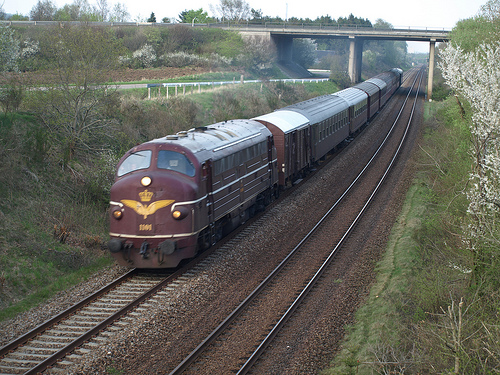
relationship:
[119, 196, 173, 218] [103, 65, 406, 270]
bird on train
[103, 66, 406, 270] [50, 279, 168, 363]
train on tracks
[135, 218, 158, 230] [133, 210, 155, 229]
1305 are numbers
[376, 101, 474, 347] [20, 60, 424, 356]
grass beside track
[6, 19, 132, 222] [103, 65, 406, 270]
trees by train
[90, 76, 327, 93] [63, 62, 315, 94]
gate in grass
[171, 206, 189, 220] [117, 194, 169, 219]
headlight by bird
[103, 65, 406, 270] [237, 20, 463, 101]
train traveling out of bridge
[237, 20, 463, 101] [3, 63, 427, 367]
bridge over railroad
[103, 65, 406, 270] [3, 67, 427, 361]
train on tracks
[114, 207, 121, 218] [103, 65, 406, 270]
headlight on train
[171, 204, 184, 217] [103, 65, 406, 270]
headlight on train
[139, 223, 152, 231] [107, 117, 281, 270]
number 1501 on engine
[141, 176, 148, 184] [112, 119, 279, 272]
headlight on engine car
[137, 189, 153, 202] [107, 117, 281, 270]
crown on engine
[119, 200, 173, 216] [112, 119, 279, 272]
wings on engine car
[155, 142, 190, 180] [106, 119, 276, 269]
window on engine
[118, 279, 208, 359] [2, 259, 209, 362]
rocks between railroad tracks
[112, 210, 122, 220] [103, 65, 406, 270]
headlight on train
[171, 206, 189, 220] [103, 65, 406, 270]
headlight on train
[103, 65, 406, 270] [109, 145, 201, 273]
train has front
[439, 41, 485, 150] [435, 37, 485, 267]
blossoms on tree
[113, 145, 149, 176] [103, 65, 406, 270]
window on train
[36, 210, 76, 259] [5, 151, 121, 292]
shrubbery in grass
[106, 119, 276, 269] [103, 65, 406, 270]
engine on train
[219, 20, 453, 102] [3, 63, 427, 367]
bridge over railroad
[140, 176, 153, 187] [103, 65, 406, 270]
headlight on train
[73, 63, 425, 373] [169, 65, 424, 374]
gravel under train tracks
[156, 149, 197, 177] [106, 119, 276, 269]
window on engine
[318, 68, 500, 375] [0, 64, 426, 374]
grass on side of railroad tracks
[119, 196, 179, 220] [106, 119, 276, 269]
design on front of engine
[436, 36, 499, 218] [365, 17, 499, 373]
blossoms on tree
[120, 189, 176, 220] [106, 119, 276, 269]
design on engine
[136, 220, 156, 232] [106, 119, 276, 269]
number 1501 on engine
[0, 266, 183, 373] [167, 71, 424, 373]
train track next to train track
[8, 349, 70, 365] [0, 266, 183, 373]
cross tie on train track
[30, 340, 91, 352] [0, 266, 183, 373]
cross tie on train track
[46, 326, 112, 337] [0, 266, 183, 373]
cross tie on train track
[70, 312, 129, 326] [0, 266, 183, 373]
cross tie on train track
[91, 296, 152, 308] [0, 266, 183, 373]
cross tie on train track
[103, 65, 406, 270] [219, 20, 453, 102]
train passing under bridge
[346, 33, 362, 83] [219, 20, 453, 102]
support on bridge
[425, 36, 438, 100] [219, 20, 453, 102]
support on bridge